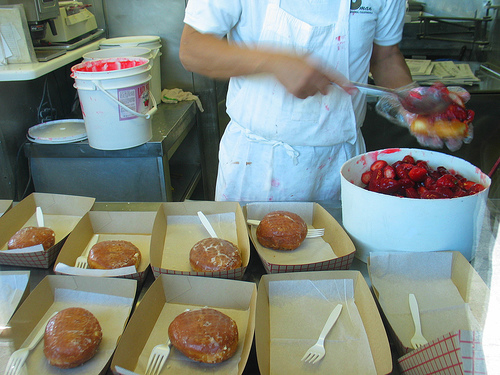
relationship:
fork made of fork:
[301, 300, 345, 365] [301, 300, 343, 363]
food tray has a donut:
[152, 198, 253, 277] [187, 238, 246, 273]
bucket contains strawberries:
[335, 144, 494, 253] [366, 163, 442, 192]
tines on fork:
[301, 352, 321, 364] [301, 300, 345, 365]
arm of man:
[167, 30, 337, 102] [174, 1, 469, 201]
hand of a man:
[268, 55, 338, 104] [174, 1, 469, 201]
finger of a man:
[331, 64, 361, 94] [174, 1, 469, 201]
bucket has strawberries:
[335, 144, 494, 253] [366, 163, 442, 192]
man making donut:
[174, 1, 469, 201] [411, 104, 474, 138]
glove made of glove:
[368, 83, 478, 150] [375, 83, 474, 150]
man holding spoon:
[174, 1, 458, 203] [359, 76, 448, 118]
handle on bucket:
[127, 91, 164, 120] [69, 59, 155, 153]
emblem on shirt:
[334, 0, 377, 20] [179, 0, 403, 139]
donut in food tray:
[187, 238, 246, 273] [152, 198, 253, 277]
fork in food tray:
[301, 300, 345, 365] [152, 198, 253, 277]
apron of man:
[221, 0, 358, 205] [174, 1, 458, 203]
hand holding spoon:
[268, 55, 338, 104] [359, 76, 448, 118]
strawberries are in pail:
[366, 163, 442, 192] [338, 149, 491, 266]